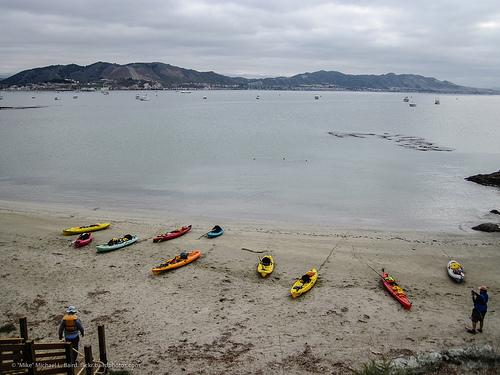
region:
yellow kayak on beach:
[282, 248, 322, 345]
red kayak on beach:
[364, 257, 419, 325]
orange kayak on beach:
[153, 242, 214, 278]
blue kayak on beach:
[208, 217, 220, 264]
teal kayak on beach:
[106, 234, 136, 268]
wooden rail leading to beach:
[7, 335, 50, 369]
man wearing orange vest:
[60, 309, 100, 352]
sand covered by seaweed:
[163, 307, 254, 357]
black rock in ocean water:
[468, 165, 496, 200]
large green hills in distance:
[123, 59, 244, 108]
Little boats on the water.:
[65, 211, 475, 336]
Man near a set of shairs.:
[25, 300, 125, 365]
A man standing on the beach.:
[455, 266, 490, 351]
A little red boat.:
[361, 252, 422, 317]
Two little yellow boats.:
[251, 236, 328, 307]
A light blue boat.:
[90, 230, 143, 255]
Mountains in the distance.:
[15, 48, 477, 94]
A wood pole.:
[90, 315, 115, 367]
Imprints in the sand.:
[202, 270, 248, 356]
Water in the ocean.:
[72, 116, 341, 187]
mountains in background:
[3, 60, 498, 100]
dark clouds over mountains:
[5, 2, 497, 75]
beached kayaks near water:
[64, 215, 470, 311]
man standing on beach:
[463, 284, 491, 333]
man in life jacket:
[54, 303, 86, 372]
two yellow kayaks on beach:
[258, 252, 320, 301]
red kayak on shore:
[377, 264, 412, 311]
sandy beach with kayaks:
[3, 200, 496, 373]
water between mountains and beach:
[8, 91, 498, 232]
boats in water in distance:
[402, 93, 442, 108]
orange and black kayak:
[147, 250, 232, 284]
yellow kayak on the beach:
[252, 253, 290, 288]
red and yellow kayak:
[364, 264, 428, 338]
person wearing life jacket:
[42, 287, 100, 357]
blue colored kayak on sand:
[87, 230, 147, 260]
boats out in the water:
[48, 72, 285, 134]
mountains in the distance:
[95, 50, 403, 118]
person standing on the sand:
[454, 276, 496, 346]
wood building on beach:
[3, 313, 150, 374]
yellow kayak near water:
[47, 184, 124, 241]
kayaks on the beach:
[47, 170, 489, 337]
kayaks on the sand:
[39, 188, 499, 373]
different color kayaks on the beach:
[54, 174, 496, 337]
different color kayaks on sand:
[28, 186, 498, 346]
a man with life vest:
[27, 285, 107, 355]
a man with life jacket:
[41, 299, 103, 362]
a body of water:
[141, 125, 230, 174]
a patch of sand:
[307, 95, 458, 178]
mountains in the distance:
[77, 46, 243, 118]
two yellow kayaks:
[247, 242, 348, 324]